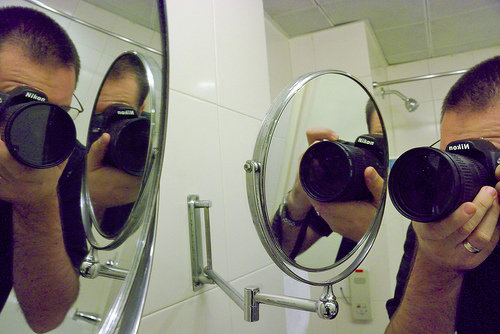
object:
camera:
[0, 85, 77, 169]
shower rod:
[381, 86, 420, 112]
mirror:
[0, 0, 172, 334]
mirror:
[243, 68, 389, 286]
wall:
[389, 1, 438, 143]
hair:
[438, 53, 499, 124]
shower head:
[404, 98, 419, 113]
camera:
[388, 137, 500, 223]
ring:
[463, 241, 480, 254]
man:
[86, 51, 149, 237]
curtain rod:
[372, 67, 472, 113]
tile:
[192, 118, 246, 254]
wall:
[184, 8, 243, 321]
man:
[368, 47, 497, 332]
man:
[0, 5, 90, 334]